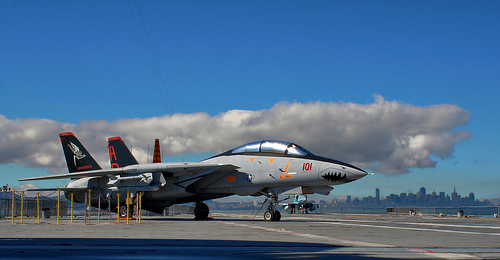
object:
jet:
[16, 131, 372, 221]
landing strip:
[0, 210, 499, 260]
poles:
[123, 190, 134, 225]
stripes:
[217, 220, 399, 247]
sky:
[0, 0, 499, 204]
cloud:
[0, 93, 475, 177]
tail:
[56, 129, 140, 204]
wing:
[17, 160, 229, 183]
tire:
[193, 200, 210, 219]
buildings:
[448, 186, 458, 209]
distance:
[0, 168, 498, 215]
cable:
[131, 0, 195, 161]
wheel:
[192, 203, 212, 218]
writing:
[302, 162, 313, 172]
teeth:
[342, 173, 349, 178]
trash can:
[41, 207, 53, 219]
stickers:
[284, 174, 295, 178]